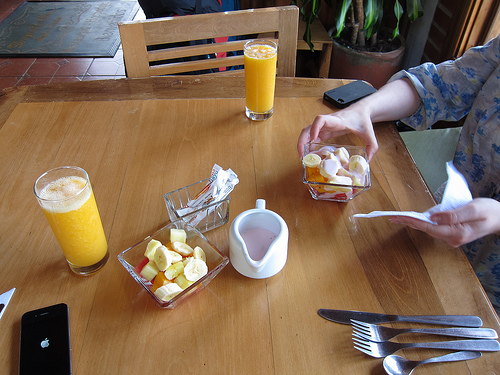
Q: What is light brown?
A: Wooden chair.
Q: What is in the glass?
A: Orange juice.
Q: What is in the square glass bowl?
A: Chopped fruit.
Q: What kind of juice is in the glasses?
A: Orange juice.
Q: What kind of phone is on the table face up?
A: Apple.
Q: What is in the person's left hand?
A: Napkin.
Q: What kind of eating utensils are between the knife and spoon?
A: Forks.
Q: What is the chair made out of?
A: Wood.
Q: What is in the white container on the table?
A: Creamer.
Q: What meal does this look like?
A: Breakfast.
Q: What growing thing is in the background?
A: Potted plant.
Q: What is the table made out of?
A: Wood.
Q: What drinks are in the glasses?
A: Orange juice.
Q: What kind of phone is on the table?
A: Apple iPhone.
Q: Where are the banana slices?
A: In the glass bowls.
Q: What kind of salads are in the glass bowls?
A: Fruit salad.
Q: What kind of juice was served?
A: Orange juice.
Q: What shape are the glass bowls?
A: Square.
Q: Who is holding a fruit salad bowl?
A: The woman.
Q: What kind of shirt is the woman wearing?
A: Blue floral shirt.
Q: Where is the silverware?
A: On the table by the woman.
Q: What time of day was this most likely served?
A: Morning.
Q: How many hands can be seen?
A: Two.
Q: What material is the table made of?
A: Wood.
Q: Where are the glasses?
A: On the table.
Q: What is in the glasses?
A: Orange juice.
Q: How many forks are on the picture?
A: Two.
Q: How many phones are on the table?
A: Two.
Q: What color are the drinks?
A: Orange.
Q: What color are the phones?
A: Black.